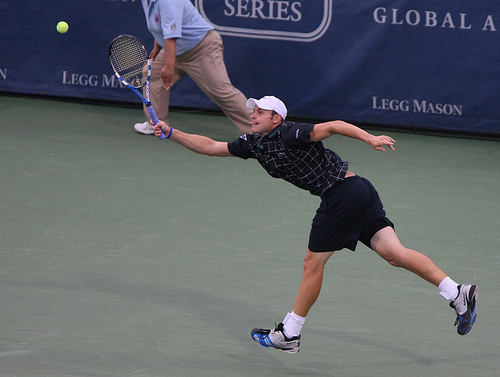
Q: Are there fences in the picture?
A: No, there are no fences.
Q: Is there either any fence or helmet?
A: No, there are no fences or helmets.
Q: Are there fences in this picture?
A: No, there are no fences.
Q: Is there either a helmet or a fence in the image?
A: No, there are no fences or helmets.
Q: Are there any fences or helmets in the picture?
A: No, there are no fences or helmets.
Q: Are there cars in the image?
A: No, there are no cars.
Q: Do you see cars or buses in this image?
A: No, there are no cars or buses.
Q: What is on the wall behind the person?
A: The word is on the wall.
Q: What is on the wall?
A: The word is on the wall.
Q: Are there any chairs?
A: No, there are no chairs.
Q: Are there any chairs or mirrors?
A: No, there are no chairs or mirrors.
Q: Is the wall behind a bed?
A: No, the wall is behind a person.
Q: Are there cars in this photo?
A: No, there are no cars.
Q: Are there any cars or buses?
A: No, there are no cars or buses.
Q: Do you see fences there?
A: No, there are no fences.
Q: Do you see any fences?
A: No, there are no fences.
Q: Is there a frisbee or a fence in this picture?
A: No, there are no fences or frisbees.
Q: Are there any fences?
A: No, there are no fences.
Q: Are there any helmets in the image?
A: No, there are no helmets.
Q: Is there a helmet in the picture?
A: No, there are no helmets.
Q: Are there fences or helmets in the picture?
A: No, there are no helmets or fences.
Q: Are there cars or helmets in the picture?
A: No, there are no cars or helmets.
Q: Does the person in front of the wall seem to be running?
A: Yes, the person is running.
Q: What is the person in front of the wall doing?
A: The person is running.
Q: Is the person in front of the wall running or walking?
A: The person is running.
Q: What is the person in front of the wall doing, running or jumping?
A: The person is running.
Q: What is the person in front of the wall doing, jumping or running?
A: The person is running.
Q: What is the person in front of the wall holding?
A: The person is holding the racket.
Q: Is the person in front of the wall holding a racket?
A: Yes, the person is holding a racket.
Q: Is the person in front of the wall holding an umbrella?
A: No, the person is holding a racket.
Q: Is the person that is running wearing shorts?
A: Yes, the person is wearing shorts.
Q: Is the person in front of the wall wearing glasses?
A: No, the person is wearing shorts.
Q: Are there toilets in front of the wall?
A: No, there is a person in front of the wall.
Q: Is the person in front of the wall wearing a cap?
A: Yes, the person is wearing a cap.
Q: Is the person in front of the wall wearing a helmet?
A: No, the person is wearing a cap.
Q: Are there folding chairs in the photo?
A: No, there are no folding chairs.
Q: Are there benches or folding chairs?
A: No, there are no folding chairs or benches.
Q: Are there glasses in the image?
A: No, there are no glasses.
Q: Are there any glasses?
A: No, there are no glasses.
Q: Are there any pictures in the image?
A: No, there are no pictures.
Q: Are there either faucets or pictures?
A: No, there are no pictures or faucets.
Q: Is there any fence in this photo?
A: No, there are no fences.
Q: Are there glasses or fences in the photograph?
A: No, there are no fences or glasses.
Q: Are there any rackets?
A: Yes, there is a racket.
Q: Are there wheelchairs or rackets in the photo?
A: Yes, there is a racket.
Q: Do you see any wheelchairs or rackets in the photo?
A: Yes, there is a racket.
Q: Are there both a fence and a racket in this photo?
A: No, there is a racket but no fences.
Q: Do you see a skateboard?
A: No, there are no skateboards.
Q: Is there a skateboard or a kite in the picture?
A: No, there are no skateboards or kites.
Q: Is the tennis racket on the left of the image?
A: Yes, the tennis racket is on the left of the image.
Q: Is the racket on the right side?
A: No, the racket is on the left of the image.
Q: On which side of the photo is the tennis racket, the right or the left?
A: The tennis racket is on the left of the image.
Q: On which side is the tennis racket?
A: The tennis racket is on the left of the image.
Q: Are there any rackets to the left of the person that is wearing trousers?
A: Yes, there is a racket to the left of the person.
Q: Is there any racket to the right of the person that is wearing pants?
A: No, the racket is to the left of the person.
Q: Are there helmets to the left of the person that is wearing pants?
A: No, there is a racket to the left of the person.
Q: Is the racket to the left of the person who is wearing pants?
A: Yes, the racket is to the left of the person.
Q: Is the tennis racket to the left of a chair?
A: No, the tennis racket is to the left of the person.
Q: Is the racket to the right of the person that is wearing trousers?
A: No, the racket is to the left of the person.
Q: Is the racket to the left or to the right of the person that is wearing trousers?
A: The racket is to the left of the person.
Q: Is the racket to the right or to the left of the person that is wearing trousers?
A: The racket is to the left of the person.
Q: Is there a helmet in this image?
A: No, there are no helmets.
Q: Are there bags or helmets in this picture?
A: No, there are no helmets or bags.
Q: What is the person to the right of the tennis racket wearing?
A: The person is wearing trousers.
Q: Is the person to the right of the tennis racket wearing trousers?
A: Yes, the person is wearing trousers.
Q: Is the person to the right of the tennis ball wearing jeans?
A: No, the person is wearing trousers.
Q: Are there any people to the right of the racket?
A: Yes, there is a person to the right of the racket.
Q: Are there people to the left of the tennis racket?
A: No, the person is to the right of the tennis racket.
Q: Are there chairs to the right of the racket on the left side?
A: No, there is a person to the right of the racket.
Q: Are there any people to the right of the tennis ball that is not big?
A: Yes, there is a person to the right of the tennis ball.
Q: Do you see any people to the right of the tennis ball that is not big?
A: Yes, there is a person to the right of the tennis ball.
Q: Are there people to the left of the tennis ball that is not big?
A: No, the person is to the right of the tennis ball.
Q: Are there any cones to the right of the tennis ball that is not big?
A: No, there is a person to the right of the tennis ball.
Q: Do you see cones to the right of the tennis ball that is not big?
A: No, there is a person to the right of the tennis ball.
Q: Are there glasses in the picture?
A: No, there are no glasses.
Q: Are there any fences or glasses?
A: No, there are no glasses or fences.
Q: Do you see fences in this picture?
A: No, there are no fences.